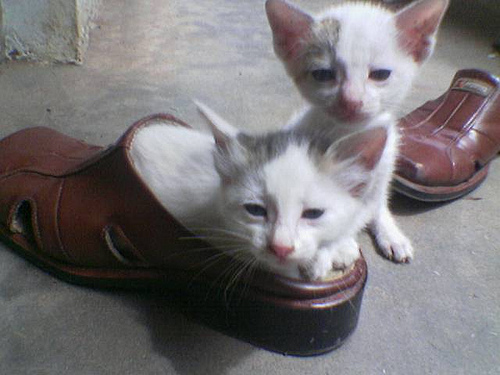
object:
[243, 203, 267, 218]
eyes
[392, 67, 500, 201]
shoe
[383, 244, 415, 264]
paw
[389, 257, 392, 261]
nail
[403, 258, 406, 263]
nail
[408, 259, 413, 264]
nail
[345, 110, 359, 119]
mouth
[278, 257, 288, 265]
mouth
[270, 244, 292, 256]
nose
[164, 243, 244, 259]
kitten whisker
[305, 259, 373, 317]
kitten whisker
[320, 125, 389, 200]
ear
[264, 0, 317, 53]
ear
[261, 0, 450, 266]
cat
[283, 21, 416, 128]
face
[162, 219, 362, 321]
whiskers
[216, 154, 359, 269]
face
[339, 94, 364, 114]
kitten's noses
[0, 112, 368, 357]
brown shoe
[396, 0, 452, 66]
cats ear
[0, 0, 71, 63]
wall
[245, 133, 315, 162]
fur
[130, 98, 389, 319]
cat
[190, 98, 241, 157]
ear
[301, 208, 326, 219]
eye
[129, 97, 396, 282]
kitten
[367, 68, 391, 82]
left eye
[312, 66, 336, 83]
eye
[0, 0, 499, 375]
photograph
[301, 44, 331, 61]
fur